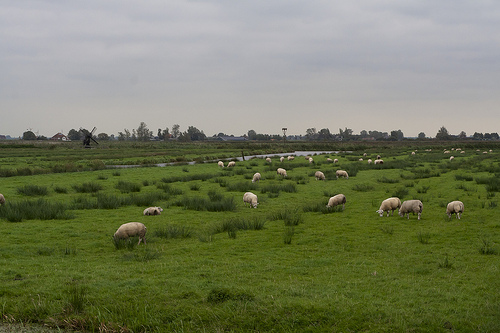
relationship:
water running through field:
[87, 147, 351, 170] [5, 138, 500, 332]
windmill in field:
[78, 124, 101, 150] [5, 138, 486, 323]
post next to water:
[237, 146, 247, 164] [90, 146, 355, 176]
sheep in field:
[395, 194, 425, 222] [5, 138, 486, 323]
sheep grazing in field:
[111, 217, 148, 247] [5, 138, 486, 323]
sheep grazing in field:
[137, 200, 167, 216] [5, 138, 486, 323]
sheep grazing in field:
[321, 190, 348, 216] [5, 138, 486, 323]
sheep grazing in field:
[372, 194, 401, 217] [5, 138, 486, 323]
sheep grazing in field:
[443, 194, 463, 221] [5, 138, 486, 323]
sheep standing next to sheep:
[374, 190, 401, 219] [395, 197, 425, 221]